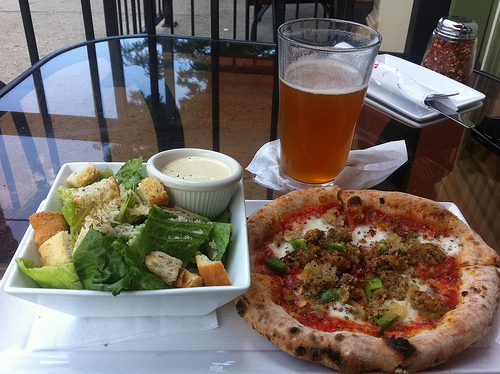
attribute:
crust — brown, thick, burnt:
[264, 334, 480, 373]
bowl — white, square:
[2, 161, 249, 317]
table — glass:
[0, 33, 499, 371]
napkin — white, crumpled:
[246, 138, 408, 190]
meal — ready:
[0, 146, 497, 373]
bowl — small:
[144, 148, 241, 216]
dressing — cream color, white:
[161, 157, 228, 179]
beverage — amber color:
[279, 64, 365, 180]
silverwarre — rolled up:
[429, 95, 477, 129]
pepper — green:
[365, 277, 383, 299]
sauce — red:
[425, 264, 459, 300]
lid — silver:
[436, 17, 479, 41]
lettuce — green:
[17, 260, 86, 290]